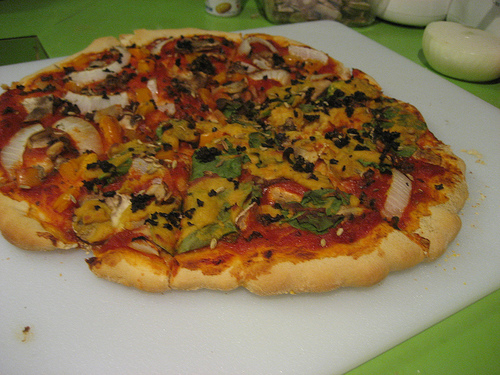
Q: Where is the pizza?
A: On a cutting board.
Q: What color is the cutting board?
A: White.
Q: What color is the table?
A: Green.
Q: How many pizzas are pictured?
A: One.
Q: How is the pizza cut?
A: In slices.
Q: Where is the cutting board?
A: On the table.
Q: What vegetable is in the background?
A: An onion.